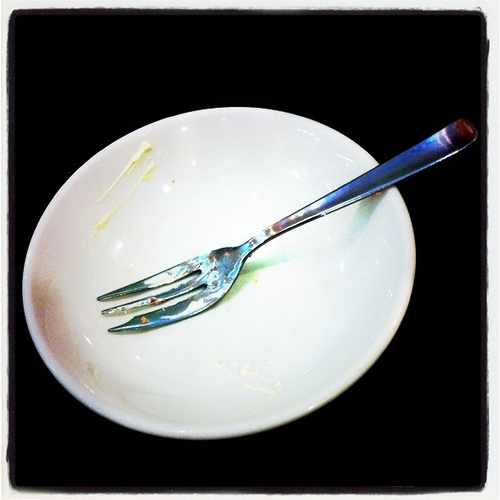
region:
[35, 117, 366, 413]
Plate is white color.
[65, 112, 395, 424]
Plate is round shape.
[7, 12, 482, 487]
Table cloth is black color.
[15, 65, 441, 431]
Plate is in table cloth.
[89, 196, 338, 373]
Fork is in plate.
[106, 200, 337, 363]
Fork is silver color.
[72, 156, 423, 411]
Light reflection on plate.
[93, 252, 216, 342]
Three pointed parts in fork.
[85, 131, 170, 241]
Yellow cream on plate.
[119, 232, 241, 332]
Fork is dirty.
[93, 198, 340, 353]
Fork on a white plate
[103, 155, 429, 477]
Fork on a white plate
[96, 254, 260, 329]
Fork on a white plate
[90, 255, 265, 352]
silver fork on a plate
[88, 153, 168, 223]
cream on a plate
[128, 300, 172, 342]
crumbs on a fork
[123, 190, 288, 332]
fork in a plate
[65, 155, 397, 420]
White color plate woth silver color fork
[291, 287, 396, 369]
White color plate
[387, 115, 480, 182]
Silver color fork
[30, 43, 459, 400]
White plate with silver color fork kept in the table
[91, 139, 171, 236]
Some eatable things in the plate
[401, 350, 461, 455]
Black color table cloth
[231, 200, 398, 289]
Shadow of the fork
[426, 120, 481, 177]
Handle of the fork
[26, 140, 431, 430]
Fork with plate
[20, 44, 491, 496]
Black color table cloth with plate and fork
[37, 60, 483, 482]
the plate is empty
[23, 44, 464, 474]
the plate is dirty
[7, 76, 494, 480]
the plate is not clean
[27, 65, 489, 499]
there is frosting on the plate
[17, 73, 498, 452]
a fork is on the plate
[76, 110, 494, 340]
the fork is dirty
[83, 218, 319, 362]
there is some food residue still on the fork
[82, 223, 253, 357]
the fork has three prongs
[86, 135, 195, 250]
yellow frosting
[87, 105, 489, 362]
a dirty fork